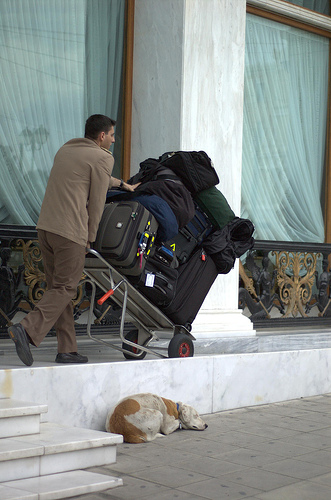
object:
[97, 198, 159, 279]
luggage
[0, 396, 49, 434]
steps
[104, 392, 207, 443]
dog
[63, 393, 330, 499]
walkway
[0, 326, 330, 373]
walkway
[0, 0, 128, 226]
curtain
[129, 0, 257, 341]
pillar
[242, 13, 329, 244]
window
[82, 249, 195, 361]
cart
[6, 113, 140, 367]
man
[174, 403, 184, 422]
collar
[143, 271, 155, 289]
tag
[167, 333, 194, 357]
wheels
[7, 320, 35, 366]
shoes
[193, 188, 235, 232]
bag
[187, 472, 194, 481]
stains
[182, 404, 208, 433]
head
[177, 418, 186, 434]
paw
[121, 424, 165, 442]
tail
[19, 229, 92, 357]
pants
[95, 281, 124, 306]
handle